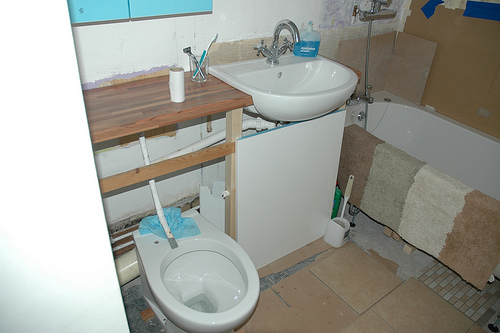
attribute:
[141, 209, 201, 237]
tissue paper — blue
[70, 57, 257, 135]
shelf — brown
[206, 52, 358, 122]
sink — white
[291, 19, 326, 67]
soap — liquid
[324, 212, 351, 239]
holder — brush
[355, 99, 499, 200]
tub — white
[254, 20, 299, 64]
faucet — silver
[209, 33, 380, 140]
sink — water faucet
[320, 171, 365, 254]
toilet cleaner — white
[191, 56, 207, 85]
cup — small, clear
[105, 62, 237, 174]
table — tall, brown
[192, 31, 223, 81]
brush — stand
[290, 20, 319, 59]
soap — blue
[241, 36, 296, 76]
handle — hot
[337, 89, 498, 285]
bath tub — NO SHOWER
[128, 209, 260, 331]
toilet — blue, white, NO WATER TANK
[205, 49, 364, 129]
sink — white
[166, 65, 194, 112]
roll — almost empty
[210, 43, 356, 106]
sink —  NO BATHROOM CUPBOARD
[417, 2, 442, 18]
tape — blue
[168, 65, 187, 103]
roll — toilet paper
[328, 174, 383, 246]
brush — cleaning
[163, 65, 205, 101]
paper roll — empty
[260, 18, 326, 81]
faucet — silver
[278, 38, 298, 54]
handle — cold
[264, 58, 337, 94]
circle — Half 